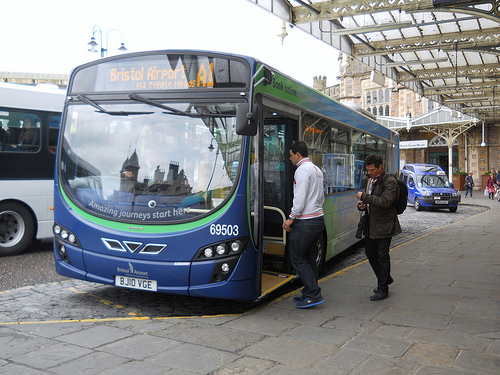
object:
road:
[0, 261, 39, 313]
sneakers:
[293, 295, 308, 304]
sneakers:
[374, 276, 394, 292]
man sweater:
[288, 157, 325, 219]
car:
[399, 163, 461, 213]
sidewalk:
[275, 325, 500, 371]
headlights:
[60, 245, 66, 253]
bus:
[53, 50, 401, 303]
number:
[209, 224, 215, 236]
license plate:
[115, 275, 157, 292]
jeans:
[288, 216, 325, 299]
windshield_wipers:
[128, 92, 235, 118]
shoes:
[370, 289, 389, 300]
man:
[464, 172, 476, 199]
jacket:
[363, 170, 402, 239]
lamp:
[118, 42, 128, 51]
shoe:
[296, 298, 326, 309]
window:
[60, 103, 246, 225]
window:
[366, 91, 372, 105]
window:
[372, 90, 378, 104]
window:
[377, 89, 383, 104]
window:
[373, 107, 378, 115]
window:
[385, 105, 390, 117]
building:
[310, 52, 499, 191]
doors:
[262, 112, 297, 296]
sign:
[111, 62, 214, 89]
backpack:
[378, 174, 408, 215]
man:
[282, 141, 328, 308]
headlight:
[54, 226, 61, 234]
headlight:
[60, 229, 68, 238]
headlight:
[68, 234, 75, 243]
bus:
[0, 82, 65, 255]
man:
[356, 153, 402, 300]